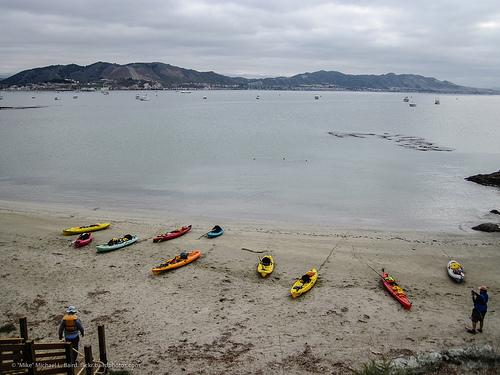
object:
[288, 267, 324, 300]
kayak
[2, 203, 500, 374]
sand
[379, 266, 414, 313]
kayak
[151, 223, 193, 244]
kayak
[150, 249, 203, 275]
kayak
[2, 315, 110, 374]
rail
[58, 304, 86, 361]
man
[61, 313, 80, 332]
vest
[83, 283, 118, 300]
seaweed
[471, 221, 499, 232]
rock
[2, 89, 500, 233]
water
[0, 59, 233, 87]
hills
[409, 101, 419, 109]
boat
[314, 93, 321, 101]
boat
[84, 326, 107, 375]
stairs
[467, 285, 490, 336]
man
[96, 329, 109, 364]
pole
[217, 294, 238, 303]
imprints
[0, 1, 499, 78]
clouds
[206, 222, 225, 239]
kayak